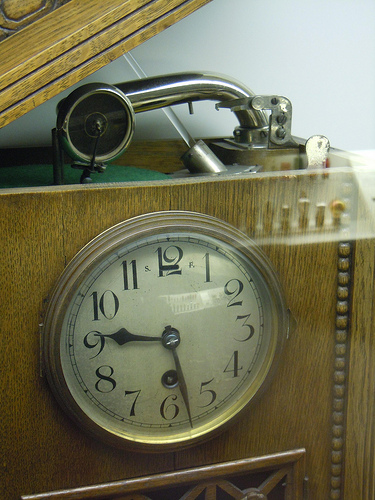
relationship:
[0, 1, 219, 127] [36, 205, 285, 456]
wooden lid on top of clock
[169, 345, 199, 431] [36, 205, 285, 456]
hand of clock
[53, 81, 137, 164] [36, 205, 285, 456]
gauge for a clock